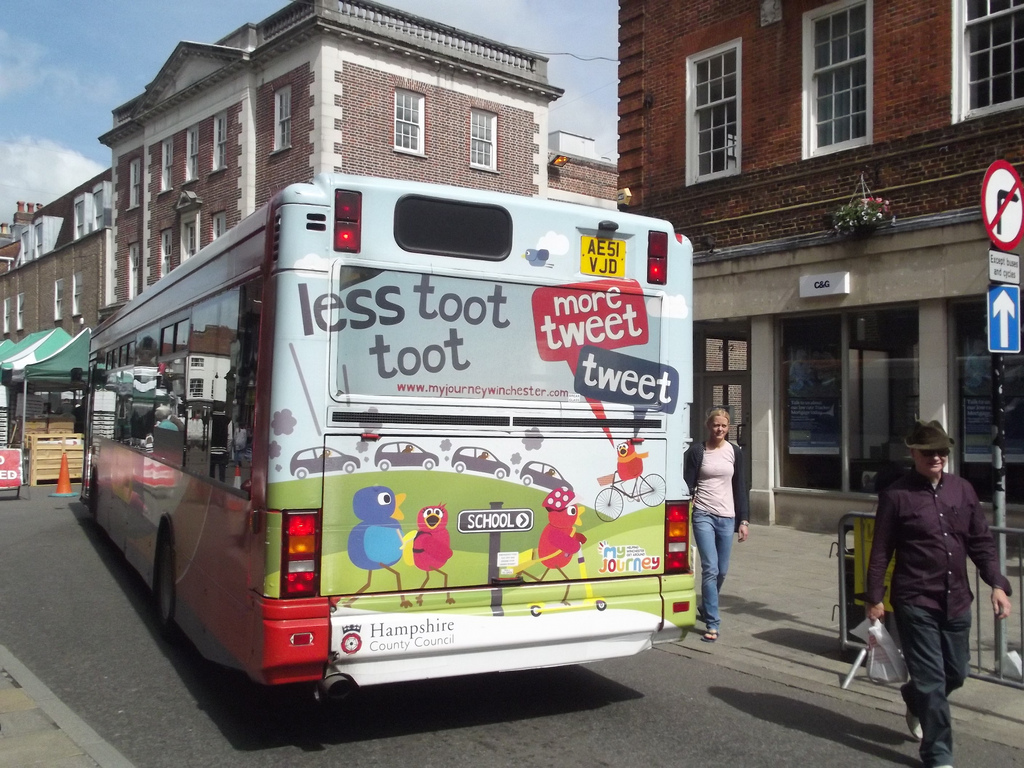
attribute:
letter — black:
[297, 273, 321, 341]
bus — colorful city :
[77, 173, 710, 731]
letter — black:
[312, 284, 354, 332]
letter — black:
[414, 269, 441, 324]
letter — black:
[375, 279, 406, 331]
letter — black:
[394, 344, 425, 375]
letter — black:
[345, 286, 378, 332]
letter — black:
[464, 286, 490, 330]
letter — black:
[293, 275, 322, 340]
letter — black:
[408, 269, 443, 324]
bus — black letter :
[300, 275, 525, 396]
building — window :
[689, 42, 728, 181]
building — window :
[799, 5, 882, 155]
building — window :
[369, 85, 426, 146]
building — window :
[391, 81, 418, 140]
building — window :
[475, 109, 497, 161]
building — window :
[268, 85, 295, 142]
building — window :
[263, 89, 298, 148]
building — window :
[209, 107, 235, 166]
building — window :
[689, 40, 744, 168]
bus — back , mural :
[317, 245, 685, 649]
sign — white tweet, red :
[544, 264, 651, 353]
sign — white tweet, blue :
[978, 262, 992, 364]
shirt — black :
[853, 472, 992, 626]